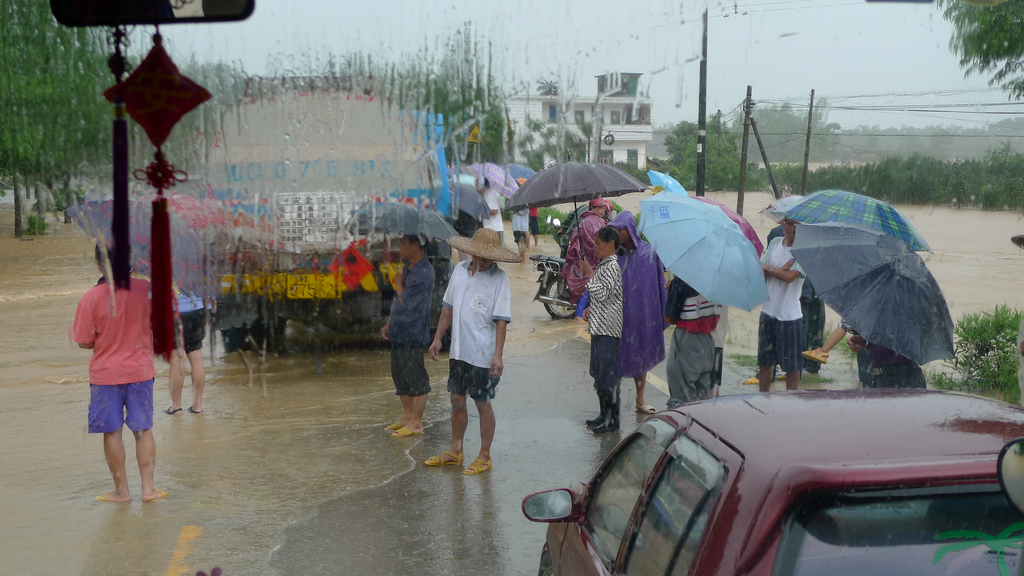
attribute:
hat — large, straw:
[445, 225, 526, 264]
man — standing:
[424, 226, 511, 480]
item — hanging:
[105, 27, 214, 359]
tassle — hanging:
[101, 26, 137, 293]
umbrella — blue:
[765, 185, 934, 255]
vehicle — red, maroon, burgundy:
[521, 386, 1023, 573]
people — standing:
[376, 229, 517, 476]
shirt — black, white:
[583, 255, 627, 342]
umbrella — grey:
[346, 196, 462, 247]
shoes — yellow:
[423, 447, 497, 474]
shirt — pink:
[72, 273, 161, 387]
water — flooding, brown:
[1, 190, 1021, 575]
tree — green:
[0, 3, 117, 239]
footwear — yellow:
[382, 414, 425, 441]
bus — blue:
[198, 92, 459, 349]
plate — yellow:
[281, 269, 347, 299]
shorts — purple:
[84, 373, 159, 435]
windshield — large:
[759, 470, 1022, 574]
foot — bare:
[95, 487, 134, 504]